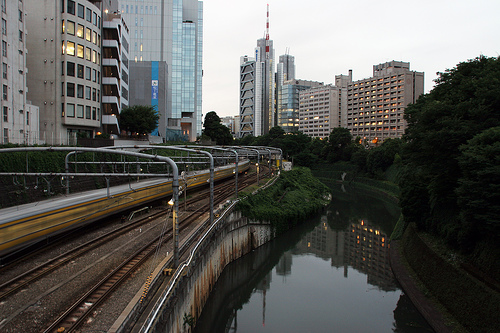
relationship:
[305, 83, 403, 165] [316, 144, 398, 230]
building of water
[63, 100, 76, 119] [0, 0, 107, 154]
window on building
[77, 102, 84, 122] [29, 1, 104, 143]
window on building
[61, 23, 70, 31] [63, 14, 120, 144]
window on building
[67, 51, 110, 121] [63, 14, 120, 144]
window on building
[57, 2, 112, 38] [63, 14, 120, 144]
window on building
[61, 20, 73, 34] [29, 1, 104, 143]
window on building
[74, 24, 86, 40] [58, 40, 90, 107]
window on building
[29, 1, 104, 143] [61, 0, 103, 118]
building with window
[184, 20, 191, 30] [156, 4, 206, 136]
window on building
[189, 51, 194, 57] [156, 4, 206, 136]
window on building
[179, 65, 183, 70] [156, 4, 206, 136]
window on building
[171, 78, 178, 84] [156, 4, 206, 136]
window on building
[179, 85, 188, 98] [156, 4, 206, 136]
window on building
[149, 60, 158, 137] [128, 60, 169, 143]
banner hanging on building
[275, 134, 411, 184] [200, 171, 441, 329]
vegetation beside river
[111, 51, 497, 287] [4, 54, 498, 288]
trees and bushes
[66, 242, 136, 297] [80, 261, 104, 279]
train tracks with gravel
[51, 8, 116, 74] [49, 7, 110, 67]
lights shining through windows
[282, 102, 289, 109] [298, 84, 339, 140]
window of building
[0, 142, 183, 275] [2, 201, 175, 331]
overhang on train tracks